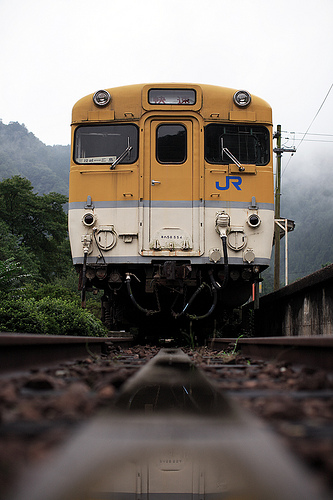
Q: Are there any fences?
A: No, there are no fences.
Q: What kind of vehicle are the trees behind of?
A: The trees are behind the bus.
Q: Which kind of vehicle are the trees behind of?
A: The trees are behind the bus.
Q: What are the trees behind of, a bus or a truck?
A: The trees are behind a bus.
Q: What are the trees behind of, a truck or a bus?
A: The trees are behind a bus.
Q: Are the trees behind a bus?
A: Yes, the trees are behind a bus.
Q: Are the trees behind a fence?
A: No, the trees are behind a bus.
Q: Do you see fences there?
A: No, there are no fences.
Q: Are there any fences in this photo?
A: No, there are no fences.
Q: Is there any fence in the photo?
A: No, there are no fences.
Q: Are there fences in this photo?
A: No, there are no fences.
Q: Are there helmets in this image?
A: No, there are no helmets.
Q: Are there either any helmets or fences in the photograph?
A: No, there are no helmets or fences.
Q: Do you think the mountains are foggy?
A: Yes, the mountains are foggy.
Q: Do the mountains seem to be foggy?
A: Yes, the mountains are foggy.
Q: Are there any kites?
A: No, there are no kites.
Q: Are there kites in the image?
A: No, there are no kites.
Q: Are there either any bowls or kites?
A: No, there are no kites or bowls.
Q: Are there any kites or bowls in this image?
A: No, there are no kites or bowls.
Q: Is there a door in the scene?
A: Yes, there is a door.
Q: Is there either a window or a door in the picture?
A: Yes, there is a door.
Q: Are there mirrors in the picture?
A: No, there are no mirrors.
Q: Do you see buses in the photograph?
A: Yes, there is a bus.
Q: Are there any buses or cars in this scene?
A: Yes, there is a bus.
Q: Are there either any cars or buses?
A: Yes, there is a bus.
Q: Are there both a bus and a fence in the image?
A: No, there is a bus but no fences.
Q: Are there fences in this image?
A: No, there are no fences.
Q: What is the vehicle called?
A: The vehicle is a bus.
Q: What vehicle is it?
A: The vehicle is a bus.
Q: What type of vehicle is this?
A: This is a bus.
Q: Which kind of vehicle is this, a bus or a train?
A: This is a bus.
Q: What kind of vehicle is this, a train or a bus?
A: This is a bus.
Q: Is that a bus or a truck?
A: That is a bus.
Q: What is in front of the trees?
A: The bus is in front of the trees.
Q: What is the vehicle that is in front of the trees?
A: The vehicle is a bus.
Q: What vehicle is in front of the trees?
A: The vehicle is a bus.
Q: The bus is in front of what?
A: The bus is in front of the trees.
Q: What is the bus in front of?
A: The bus is in front of the trees.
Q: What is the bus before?
A: The bus is in front of the trees.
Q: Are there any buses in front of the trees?
A: Yes, there is a bus in front of the trees.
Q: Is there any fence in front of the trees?
A: No, there is a bus in front of the trees.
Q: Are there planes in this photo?
A: No, there are no planes.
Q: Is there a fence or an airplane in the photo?
A: No, there are no airplanes or fences.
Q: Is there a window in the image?
A: Yes, there is a window.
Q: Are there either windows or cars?
A: Yes, there is a window.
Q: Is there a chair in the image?
A: No, there are no chairs.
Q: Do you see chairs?
A: No, there are no chairs.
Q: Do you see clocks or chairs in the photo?
A: No, there are no chairs or clocks.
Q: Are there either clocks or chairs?
A: No, there are no chairs or clocks.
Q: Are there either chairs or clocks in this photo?
A: No, there are no chairs or clocks.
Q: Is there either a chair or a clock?
A: No, there are no chairs or clocks.